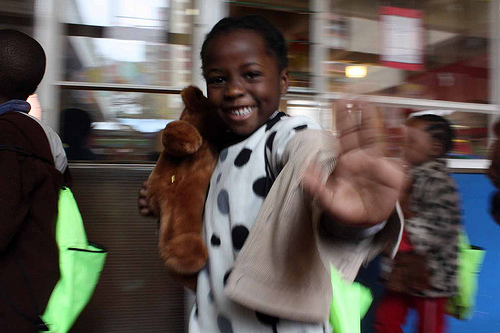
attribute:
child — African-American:
[137, 13, 408, 331]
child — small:
[192, 43, 302, 145]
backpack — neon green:
[39, 189, 104, 331]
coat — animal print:
[380, 129, 488, 301]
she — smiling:
[137, 14, 402, 331]